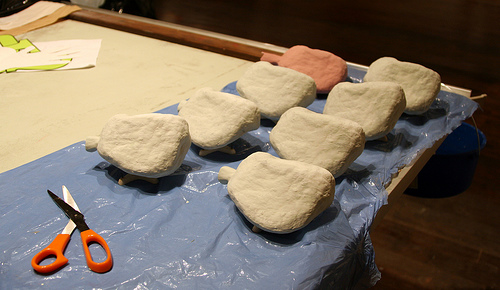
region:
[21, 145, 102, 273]
A pair of scissors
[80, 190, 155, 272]
A pair of scissors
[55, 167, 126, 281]
A pair of scissors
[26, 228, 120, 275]
Scissors have orange handles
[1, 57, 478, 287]
The drop cloth is blue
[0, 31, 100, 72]
Paper is cut out at top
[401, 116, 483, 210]
Blue bucket hangs from the table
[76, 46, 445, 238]
Eight rock shapes on drop cloth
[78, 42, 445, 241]
Seven white rock shapes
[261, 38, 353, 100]
Top left rock is pink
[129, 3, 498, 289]
Floors are hard wood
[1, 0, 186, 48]
Person is behind table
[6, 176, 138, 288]
A pair of scissors on a plastic paper.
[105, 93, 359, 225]
Ceramic objects on the table.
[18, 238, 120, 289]
The handle of the scissors are orange.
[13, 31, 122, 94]
Paper sitting in the corner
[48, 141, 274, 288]
A blue plastic bag is on the table.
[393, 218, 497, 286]
The floor is wooden.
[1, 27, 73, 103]
A green piece of papper on the table.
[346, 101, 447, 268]
The plastic bag has been ripped.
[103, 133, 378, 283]
The top of the table is covered with blue plastic.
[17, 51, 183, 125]
The top of the table is beige.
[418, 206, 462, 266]
The floor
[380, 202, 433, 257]
The floor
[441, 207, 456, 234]
The floor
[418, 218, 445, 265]
The floor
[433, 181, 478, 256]
The floor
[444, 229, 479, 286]
The floor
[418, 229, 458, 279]
The floor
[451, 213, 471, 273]
The floor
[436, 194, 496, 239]
The floor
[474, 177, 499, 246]
The floor